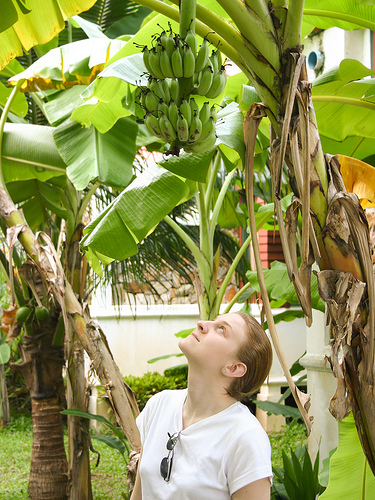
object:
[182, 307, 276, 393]
head of a person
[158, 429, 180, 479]
dark sunglasses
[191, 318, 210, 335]
nose of a person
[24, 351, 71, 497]
brown base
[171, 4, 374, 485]
banana tree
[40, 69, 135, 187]
thin green leaves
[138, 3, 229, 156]
bananas hanging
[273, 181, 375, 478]
brown banana tree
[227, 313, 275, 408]
blonde hair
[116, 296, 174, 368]
tall white fence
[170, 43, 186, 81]
bananas not ripe yet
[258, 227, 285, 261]
red building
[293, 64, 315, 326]
brown dead leaves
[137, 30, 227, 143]
banana cluster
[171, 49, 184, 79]
bananas are green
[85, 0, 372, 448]
white structure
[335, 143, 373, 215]
one yellow leaf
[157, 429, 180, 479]
hanging from t-shirt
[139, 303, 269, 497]
front of a person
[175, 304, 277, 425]
looking up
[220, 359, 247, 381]
ear of a person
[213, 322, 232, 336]
left eye of a person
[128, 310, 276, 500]
person looking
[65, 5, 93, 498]
banana tree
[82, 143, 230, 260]
leaf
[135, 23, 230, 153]
bunch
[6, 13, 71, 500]
banana tree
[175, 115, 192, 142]
bananas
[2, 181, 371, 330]
multiple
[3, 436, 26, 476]
grassy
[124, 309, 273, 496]
girl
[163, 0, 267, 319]
tree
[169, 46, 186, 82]
banana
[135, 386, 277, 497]
shirt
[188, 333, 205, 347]
mouth